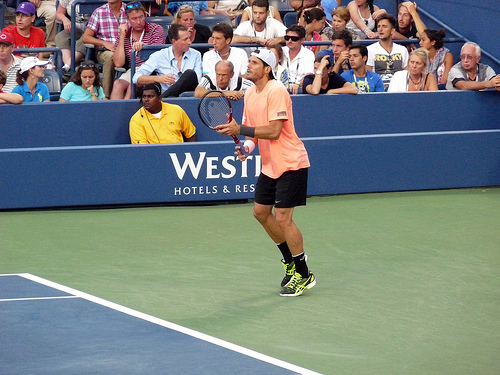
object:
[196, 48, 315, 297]
player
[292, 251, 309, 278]
socks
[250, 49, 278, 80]
cap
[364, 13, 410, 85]
man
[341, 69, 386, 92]
shirt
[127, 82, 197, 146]
man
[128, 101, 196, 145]
shirt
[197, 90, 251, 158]
racket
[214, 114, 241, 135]
hand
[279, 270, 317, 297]
shoes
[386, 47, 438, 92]
woman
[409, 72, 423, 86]
necklace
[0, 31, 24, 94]
man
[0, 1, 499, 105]
group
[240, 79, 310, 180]
shirt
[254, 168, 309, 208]
black shorts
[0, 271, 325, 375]
court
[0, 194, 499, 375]
green area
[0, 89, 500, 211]
wall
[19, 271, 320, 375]
end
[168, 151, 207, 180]
writing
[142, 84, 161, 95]
headphones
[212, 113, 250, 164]
held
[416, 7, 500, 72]
railing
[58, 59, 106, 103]
woman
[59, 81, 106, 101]
blue shirt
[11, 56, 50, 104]
woman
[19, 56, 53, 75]
white hat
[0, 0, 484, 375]
game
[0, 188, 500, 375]
floor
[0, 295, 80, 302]
lines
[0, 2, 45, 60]
man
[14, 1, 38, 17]
purple cap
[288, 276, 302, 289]
yellow laces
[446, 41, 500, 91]
man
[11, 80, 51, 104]
blue shirt